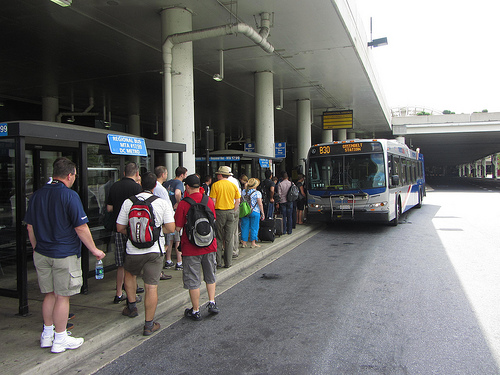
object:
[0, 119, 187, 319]
bus stop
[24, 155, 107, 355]
man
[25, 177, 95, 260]
shirt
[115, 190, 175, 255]
shirt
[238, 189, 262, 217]
shirt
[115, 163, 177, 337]
person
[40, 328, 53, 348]
white shoes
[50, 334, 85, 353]
shoes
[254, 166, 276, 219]
person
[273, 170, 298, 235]
person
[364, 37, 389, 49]
light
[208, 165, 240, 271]
man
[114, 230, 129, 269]
shorts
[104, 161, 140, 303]
man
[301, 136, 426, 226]
bus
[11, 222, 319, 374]
curb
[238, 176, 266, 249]
woman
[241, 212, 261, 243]
pants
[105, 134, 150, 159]
sign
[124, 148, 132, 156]
letters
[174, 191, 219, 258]
red shirt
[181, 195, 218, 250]
backpack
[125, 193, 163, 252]
backpack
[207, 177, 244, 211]
shirt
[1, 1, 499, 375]
station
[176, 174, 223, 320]
man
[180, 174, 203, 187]
hat